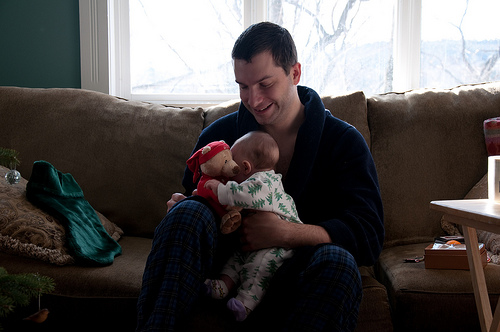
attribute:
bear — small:
[186, 138, 240, 199]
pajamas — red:
[181, 136, 230, 199]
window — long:
[127, 0, 498, 94]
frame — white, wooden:
[80, 0, 420, 111]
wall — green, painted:
[0, 0, 83, 89]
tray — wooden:
[429, 195, 499, 330]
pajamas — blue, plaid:
[206, 167, 301, 313]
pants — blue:
[145, 193, 366, 330]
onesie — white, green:
[204, 173, 306, 309]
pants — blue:
[125, 199, 360, 330]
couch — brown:
[2, 82, 498, 329]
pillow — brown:
[0, 179, 126, 266]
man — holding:
[181, 0, 387, 267]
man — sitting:
[160, 30, 395, 329]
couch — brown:
[14, 77, 498, 277]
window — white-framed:
[108, 10, 493, 116]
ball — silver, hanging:
[1, 167, 33, 193]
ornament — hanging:
[17, 270, 47, 310]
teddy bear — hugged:
[168, 147, 271, 248]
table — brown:
[430, 180, 495, 297]